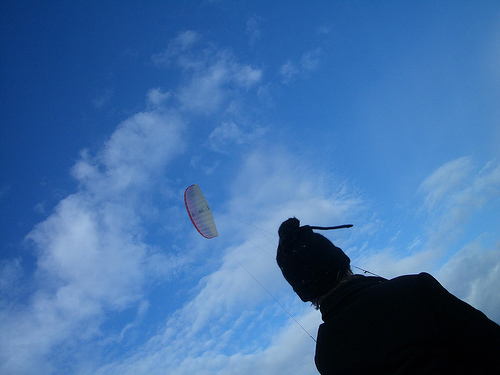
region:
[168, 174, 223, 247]
kite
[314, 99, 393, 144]
white clouds in blue sky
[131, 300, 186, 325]
white clouds in blue sky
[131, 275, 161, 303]
white clouds in blue sky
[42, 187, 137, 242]
white clouds in blue sky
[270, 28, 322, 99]
white clouds in blue sky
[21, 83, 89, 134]
white clouds in blue sky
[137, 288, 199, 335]
white clouds in blue sky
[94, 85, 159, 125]
white clouds in blue sky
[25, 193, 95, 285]
white clouds in blue sky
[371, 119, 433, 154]
white clouds in blue sky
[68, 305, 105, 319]
white clouds in blue sky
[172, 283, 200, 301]
white clouds in blue sky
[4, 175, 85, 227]
white clouds in blue sky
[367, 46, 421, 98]
white clouds in blue sky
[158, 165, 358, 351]
person is flying a kite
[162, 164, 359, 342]
person is flying a kite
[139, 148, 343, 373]
person is flying a kite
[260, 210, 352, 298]
person is wearing a cap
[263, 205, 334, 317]
person is wearing a cap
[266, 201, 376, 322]
person is wearing a cap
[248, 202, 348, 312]
person is wearing a cap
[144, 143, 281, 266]
a parasail in teh air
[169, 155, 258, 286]
a parasail in the sky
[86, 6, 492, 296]
a sky that is blue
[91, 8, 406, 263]
a sky with clouds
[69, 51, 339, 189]
a sky with white clouds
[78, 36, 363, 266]
a blue sky with clouds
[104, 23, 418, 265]
a blue sky with white cloudsq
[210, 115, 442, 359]
a parasail in the blue sky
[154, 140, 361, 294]
a parasailing flying in the sky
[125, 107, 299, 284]
a large parasail